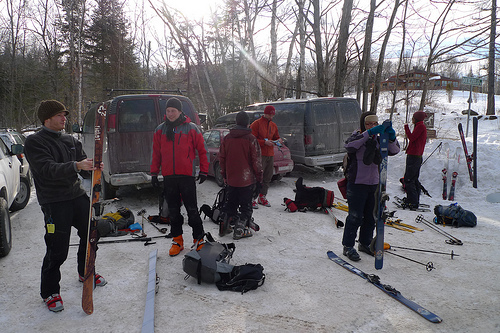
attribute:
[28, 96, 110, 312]
skier — standing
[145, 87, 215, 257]
skier — standing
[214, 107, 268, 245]
skier — standing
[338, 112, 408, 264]
skier — standing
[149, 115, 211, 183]
jacket — red, skier's, purple, red\, gre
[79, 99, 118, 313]
ski — vertical, brown, orange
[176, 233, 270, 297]
bag — laying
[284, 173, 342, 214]
bag — laying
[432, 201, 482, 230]
bag — laying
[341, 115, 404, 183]
jacket — purple, black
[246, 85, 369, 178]
van — parked, black, shiny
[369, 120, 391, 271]
ski — blue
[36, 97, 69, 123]
hat — brown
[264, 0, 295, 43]
branch — leafless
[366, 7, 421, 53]
branch — leafless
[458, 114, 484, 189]
skis — stuck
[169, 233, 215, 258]
boots — ski, orange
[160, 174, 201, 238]
pants — black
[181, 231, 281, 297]
backpack — grey, black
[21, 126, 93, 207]
jacket — black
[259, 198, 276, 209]
boot — ski, red, grey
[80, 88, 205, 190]
van — red, black, parked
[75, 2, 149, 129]
tree — large, green, tall, leafless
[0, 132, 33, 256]
vehicle — white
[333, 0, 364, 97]
tree — tall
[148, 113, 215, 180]
coat — winter, red, grey